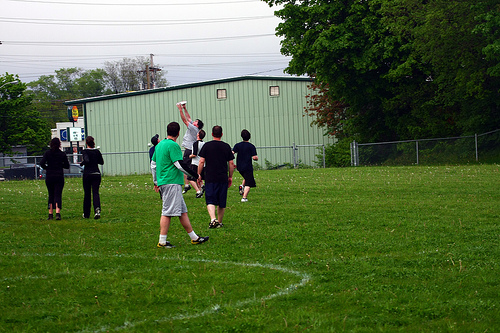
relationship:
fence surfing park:
[0, 131, 499, 179] [0, 133, 499, 328]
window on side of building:
[216, 87, 228, 99] [63, 74, 342, 175]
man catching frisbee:
[176, 101, 204, 198] [167, 95, 192, 110]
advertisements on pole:
[69, 107, 82, 161] [68, 103, 79, 174]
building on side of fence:
[63, 74, 342, 175] [0, 131, 499, 179]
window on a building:
[272, 81, 284, 97] [68, 68, 346, 173]